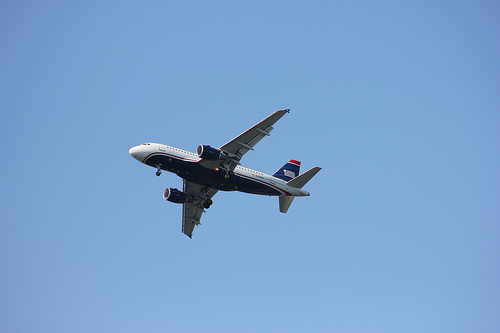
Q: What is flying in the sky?
A: An airplane.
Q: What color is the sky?
A: Blue.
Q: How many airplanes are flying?
A: One.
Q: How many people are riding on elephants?
A: Zero.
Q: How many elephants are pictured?
A: Zero.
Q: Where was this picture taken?
A: Under plane.